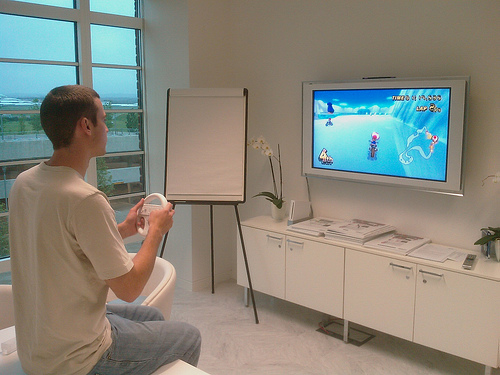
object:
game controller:
[134, 192, 168, 238]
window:
[76, 0, 139, 19]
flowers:
[247, 134, 287, 209]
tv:
[300, 77, 467, 197]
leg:
[116, 321, 202, 370]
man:
[8, 82, 201, 375]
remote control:
[462, 253, 477, 270]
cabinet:
[236, 215, 499, 374]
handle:
[265, 233, 283, 241]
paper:
[163, 86, 250, 202]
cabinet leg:
[243, 288, 250, 307]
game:
[312, 88, 450, 185]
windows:
[0, 11, 154, 259]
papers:
[286, 217, 466, 265]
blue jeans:
[90, 304, 201, 375]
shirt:
[8, 161, 134, 374]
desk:
[0, 318, 210, 375]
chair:
[104, 252, 177, 321]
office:
[0, 0, 500, 375]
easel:
[154, 86, 267, 324]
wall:
[189, 0, 500, 326]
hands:
[123, 198, 175, 240]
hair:
[39, 85, 101, 151]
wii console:
[287, 199, 311, 227]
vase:
[270, 202, 285, 223]